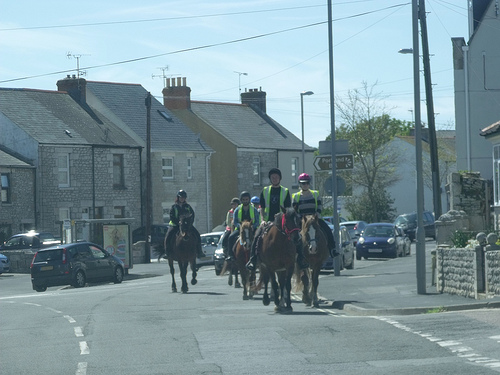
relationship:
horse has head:
[294, 212, 333, 309] [297, 209, 324, 258]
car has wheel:
[46, 246, 93, 292] [71, 270, 87, 286]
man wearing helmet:
[245, 167, 290, 268] [262, 166, 285, 182]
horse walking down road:
[294, 212, 333, 309] [0, 256, 421, 373]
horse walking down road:
[256, 203, 299, 310] [0, 256, 421, 373]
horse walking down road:
[173, 209, 198, 293] [0, 256, 421, 373]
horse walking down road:
[232, 214, 257, 299] [0, 256, 421, 373]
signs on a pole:
[313, 153, 358, 172] [323, 0, 341, 216]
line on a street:
[5, 297, 92, 373] [0, 255, 499, 374]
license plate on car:
[368, 247, 383, 252] [353, 219, 409, 257]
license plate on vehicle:
[39, 264, 52, 272] [394, 210, 435, 241]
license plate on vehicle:
[39, 264, 52, 272] [334, 220, 369, 250]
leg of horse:
[308, 267, 320, 305] [294, 212, 333, 309]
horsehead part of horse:
[276, 203, 303, 241] [228, 219, 254, 300]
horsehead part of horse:
[276, 203, 303, 241] [296, 208, 335, 308]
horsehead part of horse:
[276, 203, 303, 241] [161, 208, 207, 293]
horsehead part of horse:
[278, 210, 303, 242] [261, 205, 300, 313]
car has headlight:
[353, 219, 409, 257] [386, 236, 396, 248]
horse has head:
[246, 200, 303, 313] [237, 219, 332, 302]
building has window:
[24, 75, 147, 259] [110, 151, 129, 187]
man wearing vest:
[245, 167, 290, 268] [233, 175, 329, 234]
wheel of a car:
[115, 263, 124, 281] [30, 240, 126, 292]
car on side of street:
[353, 219, 409, 257] [3, 231, 496, 372]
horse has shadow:
[164, 212, 202, 292] [168, 280, 219, 304]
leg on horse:
[308, 267, 320, 299] [294, 212, 333, 309]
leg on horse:
[308, 267, 320, 299] [251, 199, 300, 316]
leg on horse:
[308, 267, 320, 299] [248, 199, 314, 319]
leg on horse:
[308, 267, 320, 299] [253, 208, 332, 308]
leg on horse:
[168, 258, 177, 290] [165, 212, 199, 293]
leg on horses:
[308, 267, 320, 299] [219, 203, 330, 311]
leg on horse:
[308, 267, 320, 299] [227, 222, 259, 290]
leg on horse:
[188, 259, 200, 280] [244, 155, 309, 327]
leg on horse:
[178, 259, 193, 296] [168, 210, 202, 292]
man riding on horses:
[245, 167, 290, 268] [164, 206, 331, 312]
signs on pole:
[313, 153, 353, 172] [314, 8, 353, 161]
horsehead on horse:
[276, 203, 303, 241] [231, 206, 326, 290]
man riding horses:
[245, 167, 290, 268] [218, 199, 337, 309]